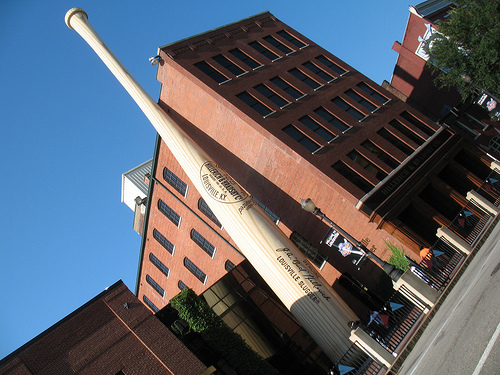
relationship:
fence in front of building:
[238, 187, 496, 364] [131, 13, 485, 341]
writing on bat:
[272, 237, 334, 312] [61, 3, 366, 368]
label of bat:
[187, 153, 263, 218] [61, 3, 366, 368]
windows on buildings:
[193, 46, 413, 194] [133, 10, 484, 257]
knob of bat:
[54, 1, 94, 29] [61, 3, 366, 368]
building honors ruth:
[118, 5, 498, 370] [65, 14, 384, 365]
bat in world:
[58, 6, 363, 368] [3, 8, 484, 368]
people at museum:
[258, 208, 474, 373] [77, 4, 457, 355]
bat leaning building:
[61, 3, 366, 368] [182, 10, 486, 234]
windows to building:
[125, 165, 190, 315] [3, 278, 203, 365]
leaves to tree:
[166, 300, 195, 326] [421, 14, 496, 101]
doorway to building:
[393, 202, 458, 259] [118, 5, 498, 370]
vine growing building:
[160, 296, 275, 362] [1, 272, 243, 369]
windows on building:
[190, 28, 436, 194] [118, 5, 498, 370]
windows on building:
[147, 225, 215, 281] [131, 13, 485, 341]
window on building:
[388, 118, 425, 143] [118, 5, 498, 370]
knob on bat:
[54, 1, 94, 29] [61, 3, 366, 368]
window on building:
[168, 186, 285, 301] [25, 25, 468, 372]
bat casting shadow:
[58, 6, 363, 368] [312, 272, 358, 370]